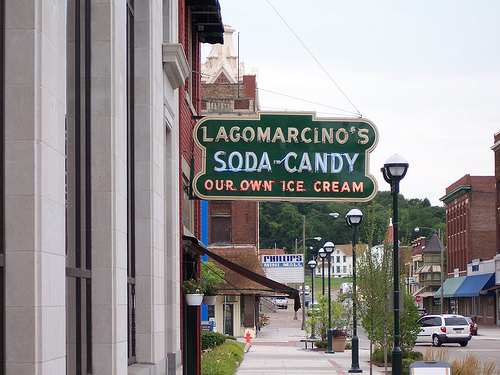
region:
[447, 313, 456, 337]
the car is white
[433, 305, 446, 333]
the car is white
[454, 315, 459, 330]
the car is white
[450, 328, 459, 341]
the car is white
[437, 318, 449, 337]
the car is white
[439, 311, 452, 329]
the car is white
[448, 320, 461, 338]
the car is white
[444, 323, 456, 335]
the car is white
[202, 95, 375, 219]
Green ice cream store sign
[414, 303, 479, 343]
White mini van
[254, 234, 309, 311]
Phillips Mini Mall sign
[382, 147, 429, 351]
Black street light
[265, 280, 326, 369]
Bench on a sidewalk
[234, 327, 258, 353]
Red fire hydrant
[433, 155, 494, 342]
Red brick building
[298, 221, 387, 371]
White house down the street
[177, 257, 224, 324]
Hanging plants on a street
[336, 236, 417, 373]
Small trees on the street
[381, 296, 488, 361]
minivan is white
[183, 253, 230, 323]
two hanging flowers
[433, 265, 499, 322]
canopies are blue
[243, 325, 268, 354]
fire hydrant is red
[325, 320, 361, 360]
large pot with flowers on the sidewalk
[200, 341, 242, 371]
flowers are yellow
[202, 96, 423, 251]
store sign is lit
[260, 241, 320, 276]
PHILLIPS written in blue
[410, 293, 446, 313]
stop sign is red and white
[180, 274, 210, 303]
hanging flowers are red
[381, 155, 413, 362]
black street lamp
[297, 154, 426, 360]
row of black street lamps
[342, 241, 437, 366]
small tree lining the road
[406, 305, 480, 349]
white van in mid-turn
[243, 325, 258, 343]
tiny red fire hydrant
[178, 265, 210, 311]
plant hanging in a white pot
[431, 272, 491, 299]
two blue awnings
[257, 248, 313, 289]
blue and white sign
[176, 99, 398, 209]
sign for a soda and candy shop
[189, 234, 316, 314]
brown awning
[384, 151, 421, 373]
a street light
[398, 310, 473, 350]
a white van on a road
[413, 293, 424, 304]
a red stop sign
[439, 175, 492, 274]
a red brick building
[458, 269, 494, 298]
a blue canopy on the front of a building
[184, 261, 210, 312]
a hanging flower plant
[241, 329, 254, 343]
a red fire hydrant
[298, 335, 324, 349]
a bench on a sidewalk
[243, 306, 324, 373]
a concrete sidewalk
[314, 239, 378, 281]
a white house on a hill